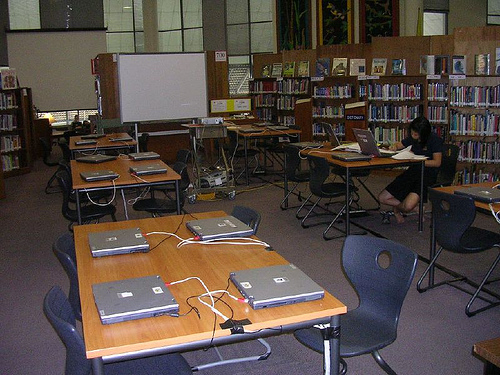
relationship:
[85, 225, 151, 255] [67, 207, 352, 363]
computer on  top of table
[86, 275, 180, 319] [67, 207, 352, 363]
computer on  top of table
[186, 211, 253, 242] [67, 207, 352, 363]
computer on  top of table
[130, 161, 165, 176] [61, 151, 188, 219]
computer on  top of table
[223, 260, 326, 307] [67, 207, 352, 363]
computer on  top of table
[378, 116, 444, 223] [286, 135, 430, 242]
girl seated desk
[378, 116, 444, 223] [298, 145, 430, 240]
girl sitting at table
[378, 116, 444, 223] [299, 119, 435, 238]
girl sitting at desk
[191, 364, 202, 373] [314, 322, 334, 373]
tape holding wires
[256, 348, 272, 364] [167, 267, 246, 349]
tape holding wires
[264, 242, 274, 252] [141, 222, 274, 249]
tape holding wires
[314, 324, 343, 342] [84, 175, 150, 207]
tape holding wires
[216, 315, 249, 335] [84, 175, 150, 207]
tape holding wires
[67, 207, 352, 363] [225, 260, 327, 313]
table with laptop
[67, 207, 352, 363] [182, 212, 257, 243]
table with laptop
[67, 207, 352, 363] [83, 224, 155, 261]
table with laptop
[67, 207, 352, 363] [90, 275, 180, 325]
table with computer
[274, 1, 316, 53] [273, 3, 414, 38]
painting on wall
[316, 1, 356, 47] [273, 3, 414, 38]
painting on wall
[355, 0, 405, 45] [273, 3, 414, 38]
painting on wall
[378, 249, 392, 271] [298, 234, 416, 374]
hole in chair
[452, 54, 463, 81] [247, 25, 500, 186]
book on top book shelves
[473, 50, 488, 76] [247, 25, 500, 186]
book on top book shelves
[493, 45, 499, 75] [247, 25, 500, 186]
book on top book shelves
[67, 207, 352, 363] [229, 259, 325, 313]
table with computer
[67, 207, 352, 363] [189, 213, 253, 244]
table with computer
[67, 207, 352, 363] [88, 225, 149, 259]
table with computer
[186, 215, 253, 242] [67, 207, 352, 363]
computer on table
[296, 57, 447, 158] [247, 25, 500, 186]
books on book shelves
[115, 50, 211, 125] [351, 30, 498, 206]
board in library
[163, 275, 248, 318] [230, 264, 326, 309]
cord from computer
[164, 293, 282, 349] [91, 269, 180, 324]
cord from laptop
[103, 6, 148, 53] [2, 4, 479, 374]
window in library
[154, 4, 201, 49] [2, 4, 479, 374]
window in library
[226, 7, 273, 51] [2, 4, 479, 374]
window in library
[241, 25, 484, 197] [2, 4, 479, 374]
book shelves in library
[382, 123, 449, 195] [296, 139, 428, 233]
girl at desk